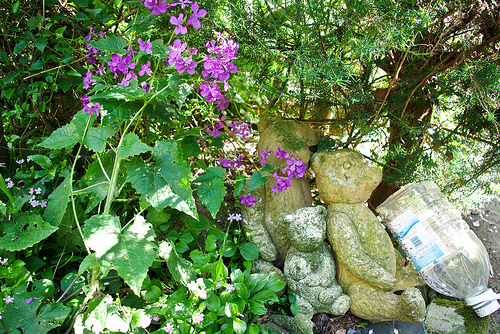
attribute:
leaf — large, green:
[85, 214, 160, 296]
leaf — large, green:
[0, 211, 58, 252]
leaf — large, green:
[41, 173, 70, 228]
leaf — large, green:
[125, 141, 199, 219]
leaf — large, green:
[0, 292, 71, 333]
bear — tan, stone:
[310, 148, 426, 323]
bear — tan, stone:
[242, 120, 323, 296]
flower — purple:
[188, 2, 206, 29]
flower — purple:
[171, 14, 189, 35]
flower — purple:
[145, 0, 166, 14]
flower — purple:
[171, 40, 188, 56]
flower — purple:
[202, 60, 225, 79]